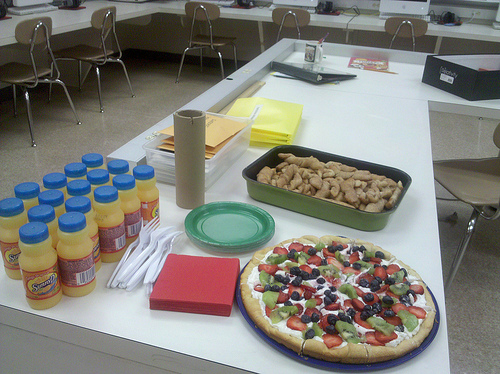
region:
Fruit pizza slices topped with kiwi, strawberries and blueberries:
[238, 234, 436, 361]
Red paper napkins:
[151, 252, 236, 317]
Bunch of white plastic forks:
[108, 215, 178, 292]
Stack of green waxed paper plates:
[185, 200, 274, 250]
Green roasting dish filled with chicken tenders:
[241, 140, 416, 234]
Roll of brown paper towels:
[172, 108, 206, 204]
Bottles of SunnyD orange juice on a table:
[1, 152, 163, 310]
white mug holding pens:
[303, 32, 328, 64]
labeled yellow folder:
[234, 96, 305, 124]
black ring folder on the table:
[271, 60, 359, 85]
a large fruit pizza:
[238, 233, 438, 365]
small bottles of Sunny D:
[0, 151, 160, 311]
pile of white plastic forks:
[103, 214, 182, 294]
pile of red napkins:
[146, 251, 242, 317]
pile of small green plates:
[181, 198, 276, 255]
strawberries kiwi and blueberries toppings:
[252, 241, 429, 349]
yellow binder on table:
[225, 95, 305, 147]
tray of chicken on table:
[241, 141, 413, 233]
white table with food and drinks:
[0, 137, 460, 372]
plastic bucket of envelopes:
[141, 103, 254, 190]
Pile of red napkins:
[146, 252, 241, 319]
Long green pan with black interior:
[242, 142, 413, 230]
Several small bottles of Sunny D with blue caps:
[0, 152, 159, 308]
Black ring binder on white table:
[267, 59, 355, 84]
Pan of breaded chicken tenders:
[242, 140, 413, 232]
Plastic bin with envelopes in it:
[142, 102, 253, 187]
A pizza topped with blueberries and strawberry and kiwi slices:
[239, 230, 435, 365]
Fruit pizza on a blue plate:
[234, 232, 441, 373]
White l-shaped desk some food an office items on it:
[0, 35, 496, 370]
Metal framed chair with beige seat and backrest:
[2, 17, 84, 147]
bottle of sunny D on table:
[17, 219, 62, 311]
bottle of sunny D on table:
[51, 208, 96, 295]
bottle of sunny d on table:
[93, 180, 126, 259]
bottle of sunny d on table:
[113, 167, 143, 242]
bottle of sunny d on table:
[132, 162, 162, 223]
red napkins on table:
[150, 252, 240, 317]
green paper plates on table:
[180, 194, 277, 248]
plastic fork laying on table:
[103, 214, 184, 290]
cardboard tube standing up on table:
[172, 107, 207, 209]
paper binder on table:
[270, 52, 357, 87]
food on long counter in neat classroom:
[5, 1, 485, 364]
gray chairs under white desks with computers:
[0, 0, 450, 142]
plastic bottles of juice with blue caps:
[0, 150, 155, 305]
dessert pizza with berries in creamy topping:
[242, 227, 437, 363]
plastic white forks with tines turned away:
[105, 215, 180, 290]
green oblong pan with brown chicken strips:
[242, 137, 412, 227]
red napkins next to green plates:
[147, 196, 272, 311]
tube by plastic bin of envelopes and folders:
[145, 95, 246, 206]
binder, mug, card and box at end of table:
[267, 30, 495, 98]